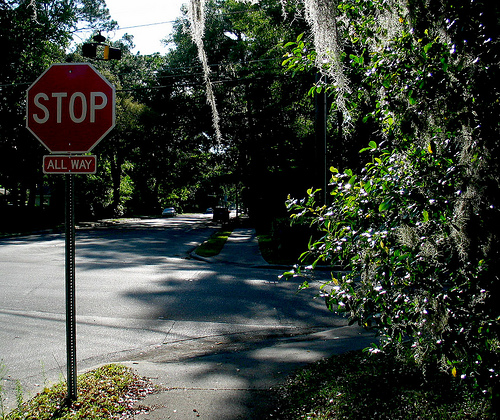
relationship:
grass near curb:
[100, 370, 133, 400] [118, 352, 161, 370]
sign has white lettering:
[21, 57, 121, 179] [46, 154, 71, 172]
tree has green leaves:
[257, 0, 500, 397] [303, 187, 320, 203]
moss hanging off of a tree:
[297, 11, 362, 131] [331, 28, 479, 351]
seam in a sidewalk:
[150, 383, 289, 394] [154, 357, 272, 418]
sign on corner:
[21, 57, 121, 179] [5, 333, 293, 418]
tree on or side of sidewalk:
[257, 6, 479, 387] [158, 325, 377, 418]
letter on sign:
[23, 86, 108, 121] [21, 57, 121, 179]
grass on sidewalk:
[11, 363, 134, 419] [116, 356, 297, 417]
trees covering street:
[2, 3, 470, 233] [11, 225, 204, 361]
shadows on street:
[109, 264, 329, 331] [10, 265, 347, 330]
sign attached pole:
[22, 58, 121, 408] [58, 184, 82, 398]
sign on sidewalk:
[22, 58, 121, 408] [22, 323, 347, 415]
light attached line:
[99, 36, 129, 66] [25, 5, 326, 43]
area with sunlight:
[196, 327, 326, 377] [135, 261, 272, 294]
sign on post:
[21, 57, 121, 179] [53, 178, 80, 403]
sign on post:
[21, 57, 121, 179] [57, 176, 80, 408]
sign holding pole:
[21, 57, 121, 179] [63, 169, 77, 401]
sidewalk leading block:
[221, 215, 261, 257] [144, 192, 236, 252]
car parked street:
[160, 199, 177, 216] [4, 208, 352, 378]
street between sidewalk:
[133, 208, 310, 318] [86, 214, 338, 414]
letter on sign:
[27, 89, 57, 130] [21, 57, 121, 179]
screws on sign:
[64, 137, 73, 173] [20, 51, 123, 175]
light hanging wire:
[26, 14, 199, 66] [12, 10, 220, 40]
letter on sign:
[64, 89, 91, 135] [22, 58, 121, 408]